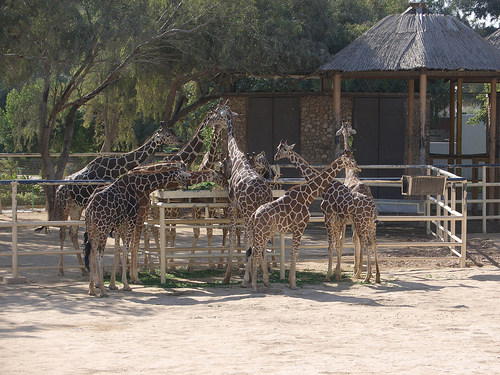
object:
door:
[376, 97, 405, 199]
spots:
[346, 205, 355, 214]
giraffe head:
[333, 120, 358, 141]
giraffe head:
[269, 136, 297, 161]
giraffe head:
[152, 120, 187, 149]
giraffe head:
[204, 99, 240, 134]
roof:
[304, 13, 499, 76]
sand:
[0, 264, 499, 372]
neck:
[222, 129, 250, 169]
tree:
[0, 0, 285, 227]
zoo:
[0, 0, 499, 374]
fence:
[0, 161, 499, 284]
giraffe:
[334, 117, 380, 283]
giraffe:
[33, 121, 188, 277]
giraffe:
[80, 165, 228, 297]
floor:
[0, 205, 499, 375]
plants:
[89, 262, 348, 289]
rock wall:
[218, 97, 429, 180]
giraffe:
[272, 138, 380, 286]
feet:
[359, 278, 370, 285]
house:
[301, 2, 500, 220]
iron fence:
[426, 162, 469, 268]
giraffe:
[202, 98, 274, 289]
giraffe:
[238, 148, 360, 292]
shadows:
[388, 272, 499, 283]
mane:
[158, 112, 211, 164]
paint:
[0, 178, 111, 186]